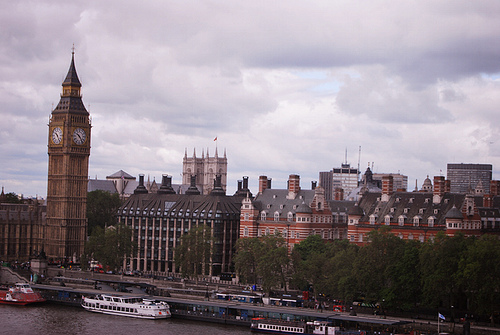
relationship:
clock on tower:
[72, 128, 86, 144] [44, 43, 93, 257]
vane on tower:
[71, 42, 77, 53] [44, 43, 93, 257]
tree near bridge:
[84, 224, 138, 271] [4, 268, 398, 333]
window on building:
[260, 211, 267, 221] [239, 175, 348, 256]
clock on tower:
[51, 127, 63, 145] [44, 43, 93, 257]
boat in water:
[82, 291, 171, 319] [0, 300, 255, 334]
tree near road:
[84, 224, 138, 271] [28, 281, 500, 331]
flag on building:
[213, 135, 219, 142] [183, 148, 227, 195]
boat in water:
[0, 283, 47, 305] [0, 300, 255, 334]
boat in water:
[249, 317, 341, 334] [0, 300, 255, 334]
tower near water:
[44, 43, 93, 257] [0, 300, 255, 334]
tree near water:
[172, 223, 222, 285] [0, 300, 255, 334]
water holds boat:
[0, 300, 255, 334] [82, 291, 171, 319]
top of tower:
[62, 55, 81, 88] [44, 43, 93, 257]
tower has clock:
[44, 43, 93, 257] [72, 128, 86, 144]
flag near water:
[439, 313, 446, 322] [0, 300, 255, 334]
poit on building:
[184, 148, 188, 158] [183, 148, 227, 195]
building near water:
[118, 193, 239, 280] [0, 300, 255, 334]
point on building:
[223, 148, 228, 158] [183, 148, 227, 195]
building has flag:
[183, 148, 227, 195] [213, 135, 219, 142]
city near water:
[1, 44, 498, 284] [0, 300, 255, 334]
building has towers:
[183, 148, 227, 195] [184, 147, 228, 157]